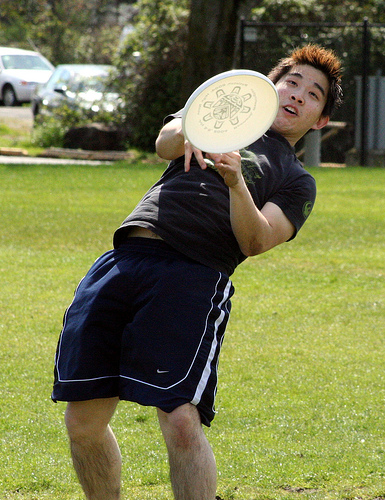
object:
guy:
[48, 43, 339, 500]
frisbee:
[182, 68, 280, 156]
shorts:
[53, 238, 236, 425]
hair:
[265, 43, 345, 117]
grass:
[0, 162, 385, 500]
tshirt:
[111, 104, 319, 279]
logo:
[155, 366, 170, 377]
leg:
[160, 402, 218, 500]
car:
[31, 64, 129, 129]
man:
[65, 81, 329, 492]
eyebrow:
[287, 71, 304, 79]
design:
[195, 79, 260, 135]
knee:
[64, 404, 107, 438]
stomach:
[119, 179, 234, 243]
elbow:
[155, 133, 167, 161]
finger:
[183, 147, 192, 173]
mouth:
[282, 103, 300, 119]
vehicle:
[0, 45, 58, 113]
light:
[19, 77, 34, 88]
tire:
[1, 85, 16, 108]